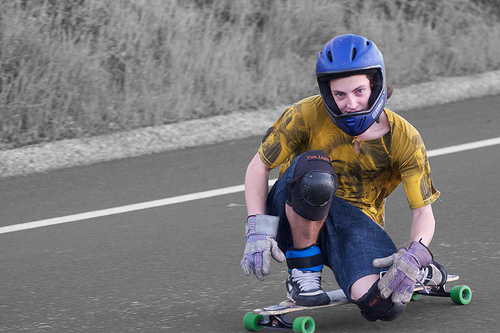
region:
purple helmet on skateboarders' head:
[315, 35, 386, 130]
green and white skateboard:
[241, 270, 471, 330]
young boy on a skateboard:
[237, 33, 444, 304]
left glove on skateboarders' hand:
[375, 240, 433, 305]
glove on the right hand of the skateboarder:
[240, 213, 285, 278]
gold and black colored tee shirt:
[256, 90, 436, 230]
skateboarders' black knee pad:
[290, 162, 335, 219]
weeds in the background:
[0, 0, 497, 151]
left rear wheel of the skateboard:
[450, 283, 472, 305]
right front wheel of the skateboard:
[240, 312, 262, 331]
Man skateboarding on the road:
[240, 32, 448, 323]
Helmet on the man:
[315, 33, 388, 136]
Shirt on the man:
[257, 93, 440, 228]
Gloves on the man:
[239, 213, 431, 305]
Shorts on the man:
[267, 150, 404, 297]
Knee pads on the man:
[286, 147, 407, 323]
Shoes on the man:
[282, 245, 446, 307]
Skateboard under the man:
[244, 273, 471, 331]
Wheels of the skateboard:
[242, 282, 472, 331]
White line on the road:
[1, 137, 498, 235]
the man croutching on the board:
[238, 2, 480, 332]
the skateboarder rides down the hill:
[233, 18, 485, 331]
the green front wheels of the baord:
[228, 305, 324, 331]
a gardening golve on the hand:
[226, 210, 290, 280]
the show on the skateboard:
[275, 258, 330, 309]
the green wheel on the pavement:
[448, 282, 482, 303]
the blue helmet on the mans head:
[313, 34, 395, 133]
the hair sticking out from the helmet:
[383, 76, 400, 102]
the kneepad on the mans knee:
[286, 148, 338, 223]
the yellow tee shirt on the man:
[256, 103, 441, 213]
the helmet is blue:
[299, 11, 419, 166]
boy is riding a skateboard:
[189, 8, 492, 330]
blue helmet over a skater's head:
[316, 33, 386, 138]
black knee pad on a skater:
[281, 149, 336, 219]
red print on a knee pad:
[302, 152, 330, 164]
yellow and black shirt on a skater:
[255, 91, 440, 227]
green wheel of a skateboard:
[290, 312, 317, 327]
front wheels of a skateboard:
[240, 306, 315, 328]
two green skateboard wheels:
[240, 310, 316, 330]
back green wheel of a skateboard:
[448, 281, 475, 303]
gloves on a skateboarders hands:
[238, 213, 433, 308]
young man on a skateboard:
[238, 33, 473, 332]